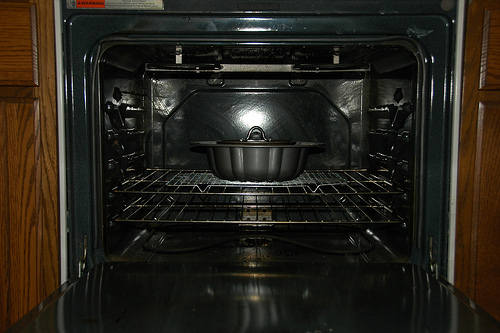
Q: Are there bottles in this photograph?
A: No, there are no bottles.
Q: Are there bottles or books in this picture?
A: No, there are no bottles or books.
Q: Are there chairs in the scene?
A: No, there are no chairs.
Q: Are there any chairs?
A: No, there are no chairs.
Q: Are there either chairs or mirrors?
A: No, there are no chairs or mirrors.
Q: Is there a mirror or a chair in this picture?
A: No, there are no chairs or mirrors.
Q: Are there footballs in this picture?
A: No, there are no footballs.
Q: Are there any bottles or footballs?
A: No, there are no footballs or bottles.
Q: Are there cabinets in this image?
A: Yes, there is a cabinet.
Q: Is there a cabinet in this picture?
A: Yes, there is a cabinet.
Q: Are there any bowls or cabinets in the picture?
A: Yes, there is a cabinet.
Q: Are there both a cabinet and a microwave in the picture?
A: No, there is a cabinet but no microwaves.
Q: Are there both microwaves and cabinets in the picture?
A: No, there is a cabinet but no microwaves.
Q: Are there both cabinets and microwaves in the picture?
A: No, there is a cabinet but no microwaves.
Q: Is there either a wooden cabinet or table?
A: Yes, there is a wood cabinet.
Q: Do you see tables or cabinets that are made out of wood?
A: Yes, the cabinet is made of wood.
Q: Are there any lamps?
A: No, there are no lamps.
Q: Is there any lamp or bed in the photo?
A: No, there are no lamps or beds.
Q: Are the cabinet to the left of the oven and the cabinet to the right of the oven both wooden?
A: Yes, both the cabinet and the cabinet are wooden.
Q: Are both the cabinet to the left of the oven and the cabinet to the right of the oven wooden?
A: Yes, both the cabinet and the cabinet are wooden.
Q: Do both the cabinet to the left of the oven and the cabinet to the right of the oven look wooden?
A: Yes, both the cabinet and the cabinet are wooden.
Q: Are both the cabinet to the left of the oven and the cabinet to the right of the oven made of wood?
A: Yes, both the cabinet and the cabinet are made of wood.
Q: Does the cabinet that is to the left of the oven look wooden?
A: Yes, the cabinet is wooden.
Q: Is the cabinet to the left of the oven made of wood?
A: Yes, the cabinet is made of wood.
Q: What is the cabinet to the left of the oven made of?
A: The cabinet is made of wood.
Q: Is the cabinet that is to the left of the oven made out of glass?
A: No, the cabinet is made of wood.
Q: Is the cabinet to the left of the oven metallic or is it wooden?
A: The cabinet is wooden.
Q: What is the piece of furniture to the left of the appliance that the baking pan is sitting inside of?
A: The piece of furniture is a cabinet.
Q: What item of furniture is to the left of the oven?
A: The piece of furniture is a cabinet.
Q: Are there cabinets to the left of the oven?
A: Yes, there is a cabinet to the left of the oven.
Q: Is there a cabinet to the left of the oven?
A: Yes, there is a cabinet to the left of the oven.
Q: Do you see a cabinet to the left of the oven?
A: Yes, there is a cabinet to the left of the oven.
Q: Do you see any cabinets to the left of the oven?
A: Yes, there is a cabinet to the left of the oven.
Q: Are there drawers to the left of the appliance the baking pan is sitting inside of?
A: No, there is a cabinet to the left of the oven.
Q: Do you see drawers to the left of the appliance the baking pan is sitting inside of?
A: No, there is a cabinet to the left of the oven.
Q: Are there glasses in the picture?
A: No, there are no glasses.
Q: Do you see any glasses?
A: No, there are no glasses.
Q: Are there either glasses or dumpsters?
A: No, there are no glasses or dumpsters.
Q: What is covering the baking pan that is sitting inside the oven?
A: The lid is covering the baking pan.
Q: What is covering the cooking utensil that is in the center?
A: The lid is covering the baking pan.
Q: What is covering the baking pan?
A: The lid is covering the baking pan.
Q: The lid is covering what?
A: The lid is covering the baking pan.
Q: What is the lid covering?
A: The lid is covering the baking pan.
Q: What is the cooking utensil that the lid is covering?
A: The cooking utensil is a baking pan.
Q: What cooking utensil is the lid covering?
A: The lid is covering the baking pan.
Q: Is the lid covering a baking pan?
A: Yes, the lid is covering a baking pan.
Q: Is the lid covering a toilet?
A: No, the lid is covering a baking pan.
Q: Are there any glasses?
A: No, there are no glasses.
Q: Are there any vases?
A: No, there are no vases.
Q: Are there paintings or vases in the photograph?
A: No, there are no vases or paintings.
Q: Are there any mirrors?
A: No, there are no mirrors.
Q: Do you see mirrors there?
A: No, there are no mirrors.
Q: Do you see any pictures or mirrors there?
A: No, there are no mirrors or pictures.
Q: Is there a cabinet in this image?
A: Yes, there is a cabinet.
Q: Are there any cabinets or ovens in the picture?
A: Yes, there is a cabinet.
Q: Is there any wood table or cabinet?
A: Yes, there is a wood cabinet.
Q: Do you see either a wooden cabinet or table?
A: Yes, there is a wood cabinet.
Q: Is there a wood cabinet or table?
A: Yes, there is a wood cabinet.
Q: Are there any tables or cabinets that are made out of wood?
A: Yes, the cabinet is made of wood.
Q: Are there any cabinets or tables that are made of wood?
A: Yes, the cabinet is made of wood.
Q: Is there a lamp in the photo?
A: No, there are no lamps.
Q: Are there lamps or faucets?
A: No, there are no lamps or faucets.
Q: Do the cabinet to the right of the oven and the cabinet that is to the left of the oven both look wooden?
A: Yes, both the cabinet and the cabinet are wooden.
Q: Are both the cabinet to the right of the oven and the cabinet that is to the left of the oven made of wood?
A: Yes, both the cabinet and the cabinet are made of wood.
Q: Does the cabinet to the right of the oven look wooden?
A: Yes, the cabinet is wooden.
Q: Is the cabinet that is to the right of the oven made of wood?
A: Yes, the cabinet is made of wood.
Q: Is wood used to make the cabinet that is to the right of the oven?
A: Yes, the cabinet is made of wood.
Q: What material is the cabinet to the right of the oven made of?
A: The cabinet is made of wood.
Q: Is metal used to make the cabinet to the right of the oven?
A: No, the cabinet is made of wood.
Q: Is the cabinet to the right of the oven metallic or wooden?
A: The cabinet is wooden.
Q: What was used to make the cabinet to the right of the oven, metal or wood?
A: The cabinet is made of wood.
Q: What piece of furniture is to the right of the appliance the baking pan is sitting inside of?
A: The piece of furniture is a cabinet.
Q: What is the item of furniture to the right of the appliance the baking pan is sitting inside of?
A: The piece of furniture is a cabinet.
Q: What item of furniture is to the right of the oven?
A: The piece of furniture is a cabinet.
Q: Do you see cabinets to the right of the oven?
A: Yes, there is a cabinet to the right of the oven.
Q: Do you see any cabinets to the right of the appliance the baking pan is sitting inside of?
A: Yes, there is a cabinet to the right of the oven.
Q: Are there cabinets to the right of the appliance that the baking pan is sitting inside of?
A: Yes, there is a cabinet to the right of the oven.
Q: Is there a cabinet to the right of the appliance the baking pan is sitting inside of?
A: Yes, there is a cabinet to the right of the oven.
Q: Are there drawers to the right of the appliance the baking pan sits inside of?
A: No, there is a cabinet to the right of the oven.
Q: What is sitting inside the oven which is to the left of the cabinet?
A: The baking pan is sitting inside the oven.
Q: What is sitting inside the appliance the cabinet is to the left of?
A: The baking pan is sitting inside the oven.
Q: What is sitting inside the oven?
A: The baking pan is sitting inside the oven.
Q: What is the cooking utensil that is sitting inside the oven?
A: The cooking utensil is a baking pan.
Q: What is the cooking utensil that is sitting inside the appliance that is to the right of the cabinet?
A: The cooking utensil is a baking pan.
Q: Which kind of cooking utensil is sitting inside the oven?
A: The cooking utensil is a baking pan.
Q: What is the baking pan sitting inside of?
A: The baking pan is sitting inside the oven.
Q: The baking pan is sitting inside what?
A: The baking pan is sitting inside the oven.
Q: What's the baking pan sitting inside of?
A: The baking pan is sitting inside the oven.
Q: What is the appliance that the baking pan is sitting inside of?
A: The appliance is an oven.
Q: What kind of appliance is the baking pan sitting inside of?
A: The baking pan is sitting inside the oven.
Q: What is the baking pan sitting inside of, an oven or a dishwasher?
A: The baking pan is sitting inside an oven.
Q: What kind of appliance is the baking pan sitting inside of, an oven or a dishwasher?
A: The baking pan is sitting inside an oven.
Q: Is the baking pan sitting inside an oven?
A: Yes, the baking pan is sitting inside an oven.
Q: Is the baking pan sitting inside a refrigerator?
A: No, the baking pan is sitting inside an oven.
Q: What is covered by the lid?
A: The baking pan is covered by the lid.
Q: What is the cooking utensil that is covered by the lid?
A: The cooking utensil is a baking pan.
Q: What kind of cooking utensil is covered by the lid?
A: The cooking utensil is a baking pan.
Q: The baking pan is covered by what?
A: The baking pan is covered by the lid.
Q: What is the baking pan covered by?
A: The baking pan is covered by the lid.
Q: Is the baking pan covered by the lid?
A: Yes, the baking pan is covered by the lid.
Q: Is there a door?
A: Yes, there is a door.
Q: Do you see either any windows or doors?
A: Yes, there is a door.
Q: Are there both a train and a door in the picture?
A: No, there is a door but no trains.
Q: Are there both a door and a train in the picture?
A: No, there is a door but no trains.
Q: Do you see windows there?
A: No, there are no windows.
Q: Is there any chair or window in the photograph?
A: No, there are no windows or chairs.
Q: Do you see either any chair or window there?
A: No, there are no windows or chairs.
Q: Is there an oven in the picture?
A: Yes, there is an oven.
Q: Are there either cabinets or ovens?
A: Yes, there is an oven.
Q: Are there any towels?
A: No, there are no towels.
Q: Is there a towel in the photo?
A: No, there are no towels.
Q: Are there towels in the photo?
A: No, there are no towels.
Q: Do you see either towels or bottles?
A: No, there are no towels or bottles.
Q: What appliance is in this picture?
A: The appliance is an oven.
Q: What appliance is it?
A: The appliance is an oven.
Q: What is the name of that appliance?
A: This is an oven.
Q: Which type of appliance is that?
A: This is an oven.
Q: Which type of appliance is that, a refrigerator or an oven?
A: This is an oven.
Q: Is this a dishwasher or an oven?
A: This is an oven.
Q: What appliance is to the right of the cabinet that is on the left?
A: The appliance is an oven.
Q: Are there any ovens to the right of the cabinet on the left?
A: Yes, there is an oven to the right of the cabinet.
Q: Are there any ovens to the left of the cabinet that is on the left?
A: No, the oven is to the right of the cabinet.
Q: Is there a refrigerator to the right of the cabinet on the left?
A: No, there is an oven to the right of the cabinet.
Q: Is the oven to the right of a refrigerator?
A: No, the oven is to the right of a cabinet.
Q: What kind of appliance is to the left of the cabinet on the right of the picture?
A: The appliance is an oven.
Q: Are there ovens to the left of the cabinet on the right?
A: Yes, there is an oven to the left of the cabinet.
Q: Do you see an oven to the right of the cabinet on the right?
A: No, the oven is to the left of the cabinet.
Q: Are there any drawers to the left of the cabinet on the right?
A: No, there is an oven to the left of the cabinet.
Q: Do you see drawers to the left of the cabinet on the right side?
A: No, there is an oven to the left of the cabinet.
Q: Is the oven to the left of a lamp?
A: No, the oven is to the left of the cabinet.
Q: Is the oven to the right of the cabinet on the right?
A: No, the oven is to the left of the cabinet.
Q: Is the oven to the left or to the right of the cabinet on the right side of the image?
A: The oven is to the left of the cabinet.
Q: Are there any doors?
A: Yes, there is a door.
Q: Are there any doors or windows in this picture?
A: Yes, there is a door.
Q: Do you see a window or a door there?
A: Yes, there is a door.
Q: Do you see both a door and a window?
A: No, there is a door but no windows.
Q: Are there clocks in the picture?
A: No, there are no clocks.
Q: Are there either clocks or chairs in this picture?
A: No, there are no clocks or chairs.